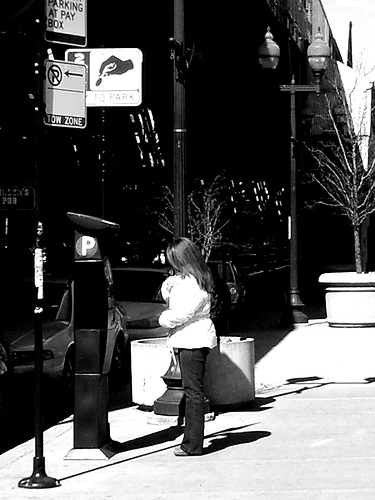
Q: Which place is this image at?
A: It is at the street.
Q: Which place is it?
A: It is a street.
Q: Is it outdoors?
A: Yes, it is outdoors.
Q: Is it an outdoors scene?
A: Yes, it is outdoors.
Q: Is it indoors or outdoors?
A: It is outdoors.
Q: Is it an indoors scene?
A: No, it is outdoors.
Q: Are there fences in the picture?
A: No, there are no fences.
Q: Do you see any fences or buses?
A: No, there are no fences or buses.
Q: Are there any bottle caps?
A: No, there are no bottle caps.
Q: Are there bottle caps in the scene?
A: No, there are no bottle caps.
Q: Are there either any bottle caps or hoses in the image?
A: No, there are no bottle caps or hoses.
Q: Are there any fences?
A: No, there are no fences.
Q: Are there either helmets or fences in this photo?
A: No, there are no fences or helmets.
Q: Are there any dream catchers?
A: No, there are no dream catchers.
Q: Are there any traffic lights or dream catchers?
A: No, there are no dream catchers or traffic lights.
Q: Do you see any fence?
A: No, there are no fences.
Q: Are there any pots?
A: Yes, there is a pot.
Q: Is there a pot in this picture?
A: Yes, there is a pot.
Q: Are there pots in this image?
A: Yes, there is a pot.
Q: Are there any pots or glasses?
A: Yes, there is a pot.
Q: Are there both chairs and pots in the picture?
A: No, there is a pot but no chairs.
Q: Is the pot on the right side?
A: Yes, the pot is on the right of the image.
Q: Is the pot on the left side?
A: No, the pot is on the right of the image.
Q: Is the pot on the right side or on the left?
A: The pot is on the right of the image.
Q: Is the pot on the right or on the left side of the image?
A: The pot is on the right of the image.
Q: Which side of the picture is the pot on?
A: The pot is on the right of the image.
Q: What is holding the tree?
A: The pot is holding the tree.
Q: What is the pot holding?
A: The pot is holding the tree.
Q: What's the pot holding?
A: The pot is holding the tree.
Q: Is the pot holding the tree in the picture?
A: Yes, the pot is holding the tree.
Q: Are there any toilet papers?
A: No, there are no toilet papers.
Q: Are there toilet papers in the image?
A: No, there are no toilet papers.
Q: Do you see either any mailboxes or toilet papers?
A: No, there are no toilet papers or mailboxes.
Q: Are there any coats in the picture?
A: Yes, there is a coat.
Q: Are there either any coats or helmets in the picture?
A: Yes, there is a coat.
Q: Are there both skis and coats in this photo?
A: No, there is a coat but no skis.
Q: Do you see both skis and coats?
A: No, there is a coat but no skis.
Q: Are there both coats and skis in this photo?
A: No, there is a coat but no skis.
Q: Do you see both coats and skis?
A: No, there is a coat but no skis.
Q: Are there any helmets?
A: No, there are no helmets.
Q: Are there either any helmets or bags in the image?
A: No, there are no helmets or bags.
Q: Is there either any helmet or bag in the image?
A: No, there are no helmets or bags.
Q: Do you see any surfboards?
A: No, there are no surfboards.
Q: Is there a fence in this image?
A: No, there are no fences.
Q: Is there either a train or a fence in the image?
A: No, there are no fences or trains.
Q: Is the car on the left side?
A: Yes, the car is on the left of the image.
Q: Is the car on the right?
A: No, the car is on the left of the image.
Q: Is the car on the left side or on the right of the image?
A: The car is on the left of the image.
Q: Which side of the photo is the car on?
A: The car is on the left of the image.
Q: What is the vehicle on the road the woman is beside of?
A: The vehicle is a car.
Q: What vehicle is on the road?
A: The vehicle is a car.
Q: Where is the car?
A: The car is on the road.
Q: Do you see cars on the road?
A: Yes, there is a car on the road.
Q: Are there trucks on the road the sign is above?
A: No, there is a car on the road.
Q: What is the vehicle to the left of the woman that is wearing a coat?
A: The vehicle is a car.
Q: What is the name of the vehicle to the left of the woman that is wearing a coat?
A: The vehicle is a car.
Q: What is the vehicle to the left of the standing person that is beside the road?
A: The vehicle is a car.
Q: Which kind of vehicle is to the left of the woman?
A: The vehicle is a car.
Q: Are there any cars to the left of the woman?
A: Yes, there is a car to the left of the woman.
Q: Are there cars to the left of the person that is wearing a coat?
A: Yes, there is a car to the left of the woman.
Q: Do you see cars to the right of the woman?
A: No, the car is to the left of the woman.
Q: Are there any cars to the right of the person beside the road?
A: No, the car is to the left of the woman.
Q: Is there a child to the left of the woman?
A: No, there is a car to the left of the woman.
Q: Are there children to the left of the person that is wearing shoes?
A: No, there is a car to the left of the woman.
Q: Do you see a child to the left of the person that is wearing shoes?
A: No, there is a car to the left of the woman.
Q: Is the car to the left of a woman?
A: Yes, the car is to the left of a woman.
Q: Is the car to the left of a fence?
A: No, the car is to the left of a woman.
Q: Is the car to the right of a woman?
A: No, the car is to the left of a woman.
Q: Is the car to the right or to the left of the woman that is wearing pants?
A: The car is to the left of the woman.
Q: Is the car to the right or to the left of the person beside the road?
A: The car is to the left of the woman.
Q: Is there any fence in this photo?
A: No, there are no fences.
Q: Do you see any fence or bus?
A: No, there are no fences or buses.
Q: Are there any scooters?
A: No, there are no scooters.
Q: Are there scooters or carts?
A: No, there are no scooters or carts.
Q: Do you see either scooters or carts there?
A: No, there are no scooters or carts.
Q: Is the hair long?
A: Yes, the hair is long.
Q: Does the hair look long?
A: Yes, the hair is long.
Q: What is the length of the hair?
A: The hair is long.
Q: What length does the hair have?
A: The hair has long length.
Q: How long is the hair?
A: The hair is long.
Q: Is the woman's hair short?
A: No, the hair is long.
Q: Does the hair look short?
A: No, the hair is long.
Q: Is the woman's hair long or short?
A: The hair is long.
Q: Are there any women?
A: Yes, there is a woman.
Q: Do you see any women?
A: Yes, there is a woman.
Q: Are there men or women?
A: Yes, there is a woman.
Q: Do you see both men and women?
A: No, there is a woman but no men.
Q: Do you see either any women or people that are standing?
A: Yes, the woman is standing.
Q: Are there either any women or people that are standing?
A: Yes, the woman is standing.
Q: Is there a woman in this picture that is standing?
A: Yes, there is a woman that is standing.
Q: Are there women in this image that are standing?
A: Yes, there is a woman that is standing.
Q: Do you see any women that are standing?
A: Yes, there is a woman that is standing.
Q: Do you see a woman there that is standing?
A: Yes, there is a woman that is standing.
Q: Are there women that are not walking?
A: Yes, there is a woman that is standing.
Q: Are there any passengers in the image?
A: No, there are no passengers.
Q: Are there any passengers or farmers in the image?
A: No, there are no passengers or farmers.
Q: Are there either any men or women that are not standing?
A: No, there is a woman but she is standing.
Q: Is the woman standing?
A: Yes, the woman is standing.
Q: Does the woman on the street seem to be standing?
A: Yes, the woman is standing.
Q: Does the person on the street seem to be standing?
A: Yes, the woman is standing.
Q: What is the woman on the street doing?
A: The woman is standing.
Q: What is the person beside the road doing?
A: The woman is standing.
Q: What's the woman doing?
A: The woman is standing.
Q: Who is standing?
A: The woman is standing.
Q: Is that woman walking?
A: No, the woman is standing.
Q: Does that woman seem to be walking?
A: No, the woman is standing.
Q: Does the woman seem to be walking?
A: No, the woman is standing.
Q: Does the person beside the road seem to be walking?
A: No, the woman is standing.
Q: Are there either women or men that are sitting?
A: No, there is a woman but she is standing.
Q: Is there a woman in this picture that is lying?
A: No, there is a woman but she is standing.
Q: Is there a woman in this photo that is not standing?
A: No, there is a woman but she is standing.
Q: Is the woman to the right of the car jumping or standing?
A: The woman is standing.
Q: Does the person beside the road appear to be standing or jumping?
A: The woman is standing.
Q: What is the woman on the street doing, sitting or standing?
A: The woman is standing.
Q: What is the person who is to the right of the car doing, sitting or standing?
A: The woman is standing.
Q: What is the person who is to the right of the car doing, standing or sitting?
A: The woman is standing.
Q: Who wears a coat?
A: The woman wears a coat.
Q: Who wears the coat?
A: The woman wears a coat.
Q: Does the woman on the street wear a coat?
A: Yes, the woman wears a coat.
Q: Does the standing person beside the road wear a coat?
A: Yes, the woman wears a coat.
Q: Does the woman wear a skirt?
A: No, the woman wears a coat.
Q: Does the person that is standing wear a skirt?
A: No, the woman wears a coat.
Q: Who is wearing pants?
A: The woman is wearing pants.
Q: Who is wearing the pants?
A: The woman is wearing pants.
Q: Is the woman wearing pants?
A: Yes, the woman is wearing pants.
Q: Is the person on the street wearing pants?
A: Yes, the woman is wearing pants.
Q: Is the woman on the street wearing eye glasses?
A: No, the woman is wearing pants.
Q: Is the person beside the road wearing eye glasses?
A: No, the woman is wearing pants.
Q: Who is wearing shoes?
A: The woman is wearing shoes.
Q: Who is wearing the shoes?
A: The woman is wearing shoes.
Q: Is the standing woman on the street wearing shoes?
A: Yes, the woman is wearing shoes.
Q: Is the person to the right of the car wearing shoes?
A: Yes, the woman is wearing shoes.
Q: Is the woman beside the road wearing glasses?
A: No, the woman is wearing shoes.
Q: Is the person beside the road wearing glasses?
A: No, the woman is wearing shoes.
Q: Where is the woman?
A: The woman is on the street.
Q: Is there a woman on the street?
A: Yes, there is a woman on the street.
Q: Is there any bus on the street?
A: No, there is a woman on the street.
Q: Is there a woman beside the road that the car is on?
A: Yes, there is a woman beside the road.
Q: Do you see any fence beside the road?
A: No, there is a woman beside the road.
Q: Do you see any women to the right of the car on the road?
A: Yes, there is a woman to the right of the car.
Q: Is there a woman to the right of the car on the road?
A: Yes, there is a woman to the right of the car.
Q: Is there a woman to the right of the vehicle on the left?
A: Yes, there is a woman to the right of the car.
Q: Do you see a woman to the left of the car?
A: No, the woman is to the right of the car.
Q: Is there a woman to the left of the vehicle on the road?
A: No, the woman is to the right of the car.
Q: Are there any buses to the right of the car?
A: No, there is a woman to the right of the car.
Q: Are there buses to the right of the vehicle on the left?
A: No, there is a woman to the right of the car.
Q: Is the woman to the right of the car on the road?
A: Yes, the woman is to the right of the car.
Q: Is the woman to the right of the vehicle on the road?
A: Yes, the woman is to the right of the car.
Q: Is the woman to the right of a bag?
A: No, the woman is to the right of the car.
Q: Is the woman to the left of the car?
A: No, the woman is to the right of the car.